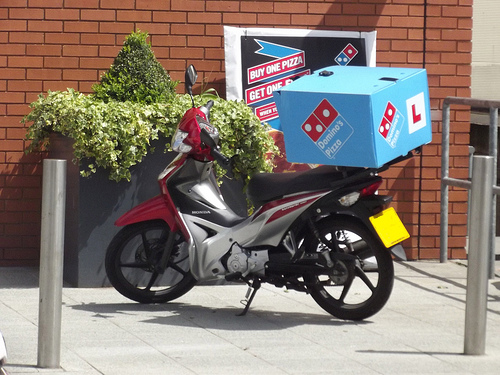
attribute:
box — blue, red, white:
[260, 61, 431, 162]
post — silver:
[31, 148, 81, 365]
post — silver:
[462, 150, 496, 358]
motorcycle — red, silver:
[101, 55, 436, 331]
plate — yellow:
[366, 201, 409, 255]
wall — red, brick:
[3, 3, 473, 264]